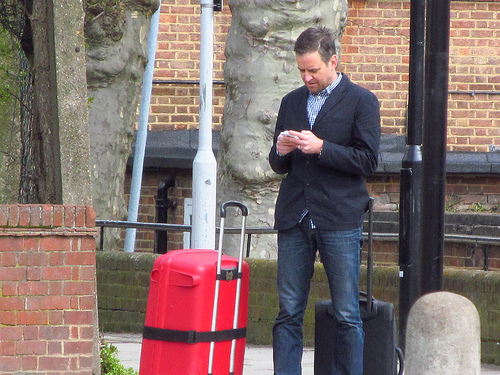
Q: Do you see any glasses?
A: No, there are no glasses.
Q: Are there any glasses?
A: No, there are no glasses.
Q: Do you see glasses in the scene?
A: No, there are no glasses.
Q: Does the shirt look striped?
A: Yes, the shirt is striped.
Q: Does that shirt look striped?
A: Yes, the shirt is striped.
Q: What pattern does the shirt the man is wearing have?
A: The shirt has striped pattern.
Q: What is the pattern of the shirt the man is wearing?
A: The shirt is striped.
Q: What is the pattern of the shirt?
A: The shirt is striped.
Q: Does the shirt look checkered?
A: No, the shirt is striped.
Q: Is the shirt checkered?
A: No, the shirt is striped.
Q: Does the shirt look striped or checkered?
A: The shirt is striped.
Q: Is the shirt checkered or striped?
A: The shirt is striped.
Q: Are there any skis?
A: No, there are no skis.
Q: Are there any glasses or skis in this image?
A: No, there are no skis or glasses.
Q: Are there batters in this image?
A: No, there are no batters.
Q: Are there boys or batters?
A: No, there are no batters or boys.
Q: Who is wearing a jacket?
A: The man is wearing a jacket.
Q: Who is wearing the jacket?
A: The man is wearing a jacket.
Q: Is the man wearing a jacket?
A: Yes, the man is wearing a jacket.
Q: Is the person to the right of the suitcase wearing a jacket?
A: Yes, the man is wearing a jacket.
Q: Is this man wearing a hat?
A: No, the man is wearing a jacket.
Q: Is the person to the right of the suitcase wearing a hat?
A: No, the man is wearing a jacket.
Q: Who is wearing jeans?
A: The man is wearing jeans.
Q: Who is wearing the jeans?
A: The man is wearing jeans.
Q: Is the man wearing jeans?
A: Yes, the man is wearing jeans.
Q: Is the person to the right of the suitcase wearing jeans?
A: Yes, the man is wearing jeans.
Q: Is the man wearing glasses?
A: No, the man is wearing jeans.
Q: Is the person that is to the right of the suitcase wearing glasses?
A: No, the man is wearing jeans.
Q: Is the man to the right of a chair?
A: No, the man is to the right of the suitcase.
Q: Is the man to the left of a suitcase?
A: No, the man is to the right of a suitcase.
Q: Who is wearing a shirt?
A: The man is wearing a shirt.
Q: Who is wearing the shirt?
A: The man is wearing a shirt.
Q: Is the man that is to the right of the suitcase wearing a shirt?
A: Yes, the man is wearing a shirt.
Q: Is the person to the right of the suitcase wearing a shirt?
A: Yes, the man is wearing a shirt.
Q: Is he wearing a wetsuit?
A: No, the man is wearing a shirt.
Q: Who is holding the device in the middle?
A: The man is holding the cell phone.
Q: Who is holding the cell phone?
A: The man is holding the cell phone.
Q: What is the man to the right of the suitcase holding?
A: The man is holding the cell phone.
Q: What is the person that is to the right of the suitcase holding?
A: The man is holding the cell phone.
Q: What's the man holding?
A: The man is holding the cell phone.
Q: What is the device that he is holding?
A: The device is a cell phone.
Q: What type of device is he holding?
A: The man is holding the cell phone.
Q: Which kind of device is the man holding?
A: The man is holding the cell phone.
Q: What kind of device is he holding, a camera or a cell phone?
A: The man is holding a cell phone.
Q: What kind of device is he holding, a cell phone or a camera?
A: The man is holding a cell phone.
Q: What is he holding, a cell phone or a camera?
A: The man is holding a cell phone.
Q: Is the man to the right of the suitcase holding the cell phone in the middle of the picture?
A: Yes, the man is holding the cellphone.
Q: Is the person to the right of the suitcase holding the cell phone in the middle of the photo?
A: Yes, the man is holding the cellphone.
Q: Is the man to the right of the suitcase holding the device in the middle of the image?
A: Yes, the man is holding the cellphone.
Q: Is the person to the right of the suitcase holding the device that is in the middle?
A: Yes, the man is holding the cellphone.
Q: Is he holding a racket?
A: No, the man is holding the cellphone.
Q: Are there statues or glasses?
A: No, there are no glasses or statues.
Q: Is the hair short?
A: Yes, the hair is short.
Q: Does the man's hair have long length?
A: No, the hair is short.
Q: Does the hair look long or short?
A: The hair is short.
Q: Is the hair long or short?
A: The hair is short.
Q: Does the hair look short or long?
A: The hair is short.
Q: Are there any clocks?
A: No, there are no clocks.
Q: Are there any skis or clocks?
A: No, there are no clocks or skis.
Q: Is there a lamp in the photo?
A: No, there are no lamps.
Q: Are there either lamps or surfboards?
A: No, there are no lamps or surfboards.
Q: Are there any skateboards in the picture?
A: No, there are no skateboards.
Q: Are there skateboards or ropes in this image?
A: No, there are no skateboards or ropes.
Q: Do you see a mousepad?
A: No, there are no mouse pads.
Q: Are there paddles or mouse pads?
A: No, there are no mouse pads or paddles.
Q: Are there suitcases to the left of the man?
A: Yes, there is a suitcase to the left of the man.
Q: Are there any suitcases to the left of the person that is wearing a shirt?
A: Yes, there is a suitcase to the left of the man.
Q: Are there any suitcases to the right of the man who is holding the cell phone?
A: No, the suitcase is to the left of the man.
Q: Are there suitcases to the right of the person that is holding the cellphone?
A: No, the suitcase is to the left of the man.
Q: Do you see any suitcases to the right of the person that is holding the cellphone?
A: No, the suitcase is to the left of the man.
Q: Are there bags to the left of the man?
A: No, there is a suitcase to the left of the man.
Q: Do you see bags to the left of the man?
A: No, there is a suitcase to the left of the man.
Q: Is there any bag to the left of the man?
A: No, there is a suitcase to the left of the man.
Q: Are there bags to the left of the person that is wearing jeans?
A: No, there is a suitcase to the left of the man.